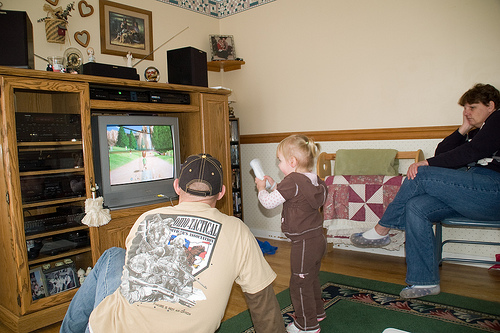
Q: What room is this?
A: Living room.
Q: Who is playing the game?
A: The little girl.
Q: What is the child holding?
A: A video game controller.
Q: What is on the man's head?
A: A hat.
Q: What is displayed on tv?
A: Video game.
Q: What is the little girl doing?
A: Playing a game.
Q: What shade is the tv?
A: Gray.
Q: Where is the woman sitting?
A: Corner.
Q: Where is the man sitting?
A: Floor.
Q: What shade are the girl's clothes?
A: Brown.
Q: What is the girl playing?
A: Video game.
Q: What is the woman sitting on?
A: Chair.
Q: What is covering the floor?
A: Rug.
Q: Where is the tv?
A: Stand.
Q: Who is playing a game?
A: A girl.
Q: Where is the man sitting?
A: On the floor.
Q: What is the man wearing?
A: A hat.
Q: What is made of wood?
A: Border of the wall.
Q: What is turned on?
A: The television.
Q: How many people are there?
A: Three.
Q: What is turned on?
A: Television.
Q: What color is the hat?
A: Black.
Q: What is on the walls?
A: Paintings.